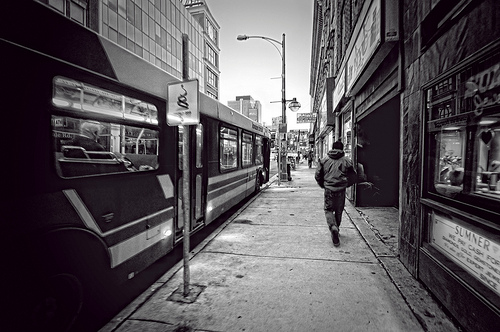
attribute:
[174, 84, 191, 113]
sign — black, white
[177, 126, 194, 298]
pole — metal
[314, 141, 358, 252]
person — walking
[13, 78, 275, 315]
bus — striped, stopped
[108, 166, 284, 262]
lines — white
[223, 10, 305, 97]
sky — clear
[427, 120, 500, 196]
windows — small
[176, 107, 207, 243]
door — closed